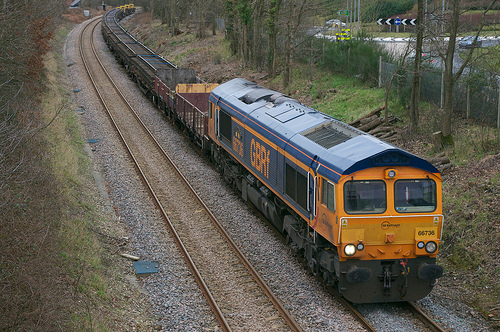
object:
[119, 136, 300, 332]
rail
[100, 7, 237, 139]
train cars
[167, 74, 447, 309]
engine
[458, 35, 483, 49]
car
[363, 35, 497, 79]
road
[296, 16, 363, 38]
train tracks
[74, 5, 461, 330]
train track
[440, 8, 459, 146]
tree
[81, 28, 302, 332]
tracks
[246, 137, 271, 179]
logo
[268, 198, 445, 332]
track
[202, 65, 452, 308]
train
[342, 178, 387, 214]
window